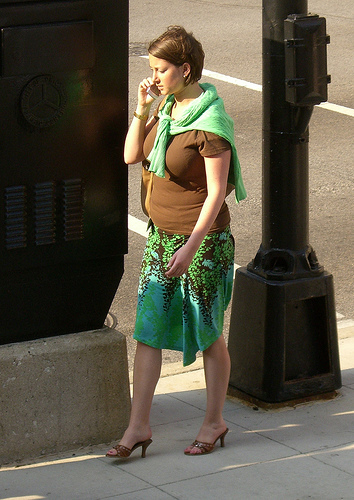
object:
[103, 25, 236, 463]
woman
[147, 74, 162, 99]
phone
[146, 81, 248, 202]
sweater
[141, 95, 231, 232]
teeshirt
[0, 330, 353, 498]
sidewalk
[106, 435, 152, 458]
sandals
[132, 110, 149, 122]
watch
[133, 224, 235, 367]
skirt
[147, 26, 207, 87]
hair